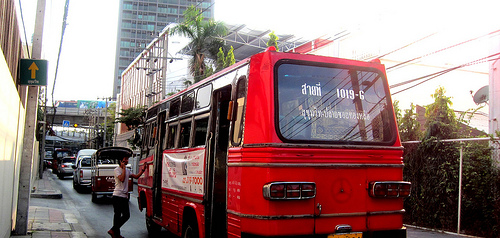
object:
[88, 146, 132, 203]
car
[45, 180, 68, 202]
curb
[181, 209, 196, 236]
tire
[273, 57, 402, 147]
windshield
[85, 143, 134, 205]
vehicle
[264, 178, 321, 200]
light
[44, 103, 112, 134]
bridge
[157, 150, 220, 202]
sign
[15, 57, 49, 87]
sign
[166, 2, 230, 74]
tree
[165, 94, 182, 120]
window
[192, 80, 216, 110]
window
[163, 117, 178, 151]
window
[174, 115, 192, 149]
window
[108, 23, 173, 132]
facade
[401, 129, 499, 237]
greentree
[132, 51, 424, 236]
window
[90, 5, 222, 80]
apartment building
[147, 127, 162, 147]
window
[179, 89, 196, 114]
window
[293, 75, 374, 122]
writing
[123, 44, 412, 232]
bus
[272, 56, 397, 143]
window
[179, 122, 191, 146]
window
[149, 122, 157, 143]
window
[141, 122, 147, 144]
window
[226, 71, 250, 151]
window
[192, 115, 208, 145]
window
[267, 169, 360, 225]
brake light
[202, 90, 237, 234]
door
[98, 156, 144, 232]
person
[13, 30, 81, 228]
wall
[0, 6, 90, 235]
building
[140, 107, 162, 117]
window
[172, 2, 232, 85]
palm tree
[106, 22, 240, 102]
building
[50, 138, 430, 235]
road